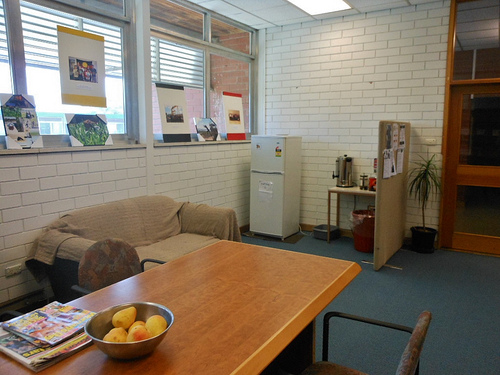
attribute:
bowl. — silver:
[80, 300, 180, 346]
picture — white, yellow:
[54, 24, 114, 109]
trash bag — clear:
[344, 199, 390, 271]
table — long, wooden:
[176, 249, 257, 311]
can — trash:
[346, 198, 381, 264]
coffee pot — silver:
[331, 154, 355, 190]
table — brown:
[2, 239, 360, 371]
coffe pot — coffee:
[331, 153, 354, 188]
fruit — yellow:
[115, 307, 135, 319]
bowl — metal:
[121, 339, 148, 361]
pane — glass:
[457, 93, 497, 169]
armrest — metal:
[317, 308, 413, 360]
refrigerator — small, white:
[251, 135, 303, 232]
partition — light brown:
[367, 115, 415, 271]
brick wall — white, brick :
[259, 0, 439, 246]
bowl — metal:
[80, 298, 177, 360]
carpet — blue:
[400, 274, 475, 311]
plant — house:
[409, 154, 441, 234]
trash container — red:
[353, 207, 376, 252]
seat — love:
[71, 201, 166, 261]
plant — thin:
[419, 157, 444, 229]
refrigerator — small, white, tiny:
[244, 130, 306, 243]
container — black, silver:
[330, 142, 354, 188]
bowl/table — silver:
[85, 293, 212, 370]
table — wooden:
[64, 237, 358, 365]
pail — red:
[347, 208, 380, 255]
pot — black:
[407, 225, 435, 255]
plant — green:
[408, 153, 447, 251]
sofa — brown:
[3, 183, 263, 299]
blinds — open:
[153, 45, 208, 88]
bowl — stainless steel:
[80, 328, 170, 353]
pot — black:
[408, 230, 439, 260]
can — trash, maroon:
[351, 206, 371, 249]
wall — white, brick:
[270, 25, 439, 225]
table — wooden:
[13, 230, 363, 365]